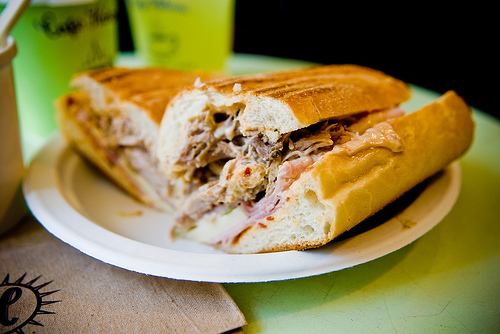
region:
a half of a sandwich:
[153, 65, 468, 236]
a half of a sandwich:
[56, 54, 183, 197]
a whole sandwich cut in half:
[57, 51, 457, 248]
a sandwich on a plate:
[69, 77, 369, 272]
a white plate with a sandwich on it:
[135, 86, 437, 308]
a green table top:
[391, 282, 443, 319]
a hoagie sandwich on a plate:
[51, 67, 171, 182]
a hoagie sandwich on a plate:
[157, 75, 410, 264]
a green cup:
[130, 5, 239, 58]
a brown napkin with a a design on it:
[6, 260, 71, 332]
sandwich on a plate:
[5, 52, 487, 302]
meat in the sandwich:
[185, 117, 367, 239]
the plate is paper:
[2, 118, 477, 301]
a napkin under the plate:
[6, 176, 261, 328]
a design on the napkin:
[0, 265, 61, 332]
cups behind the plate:
[5, 4, 263, 136]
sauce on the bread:
[326, 114, 424, 165]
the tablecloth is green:
[15, 32, 495, 330]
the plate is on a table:
[13, 17, 498, 331]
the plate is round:
[0, 57, 482, 287]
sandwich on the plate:
[75, 57, 421, 232]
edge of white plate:
[213, 256, 262, 298]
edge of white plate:
[269, 255, 296, 280]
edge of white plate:
[119, 252, 135, 277]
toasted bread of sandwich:
[268, 162, 364, 257]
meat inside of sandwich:
[213, 146, 269, 212]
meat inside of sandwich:
[247, 136, 274, 167]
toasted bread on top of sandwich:
[281, 84, 343, 131]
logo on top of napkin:
[6, 271, 66, 326]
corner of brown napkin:
[221, 305, 255, 323]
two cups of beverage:
[7, 0, 264, 125]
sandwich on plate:
[21, 58, 487, 277]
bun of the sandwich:
[65, 56, 488, 255]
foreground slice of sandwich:
[166, 64, 474, 248]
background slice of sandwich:
[61, 54, 226, 204]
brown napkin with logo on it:
[1, 196, 258, 333]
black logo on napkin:
[2, 267, 65, 332]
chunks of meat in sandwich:
[178, 121, 364, 230]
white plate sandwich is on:
[21, 102, 477, 292]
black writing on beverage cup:
[34, 4, 127, 69]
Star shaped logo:
[0, 269, 62, 331]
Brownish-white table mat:
[0, 236, 249, 332]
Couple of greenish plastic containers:
[0, 0, 237, 172]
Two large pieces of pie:
[52, 59, 476, 258]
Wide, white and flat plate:
[20, 129, 461, 284]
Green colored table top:
[5, 64, 497, 329]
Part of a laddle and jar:
[0, 2, 35, 241]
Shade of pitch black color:
[239, 1, 499, 52]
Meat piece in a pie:
[220, 157, 265, 205]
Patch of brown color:
[120, 72, 175, 99]